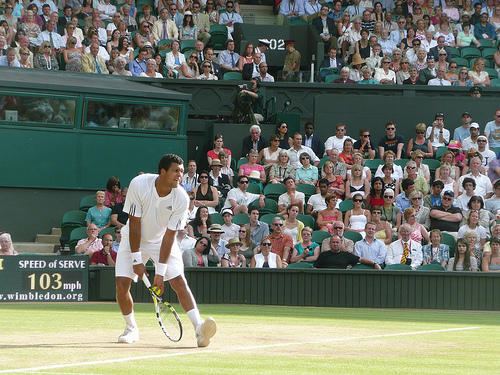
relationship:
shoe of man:
[175, 309, 232, 355] [83, 122, 229, 344]